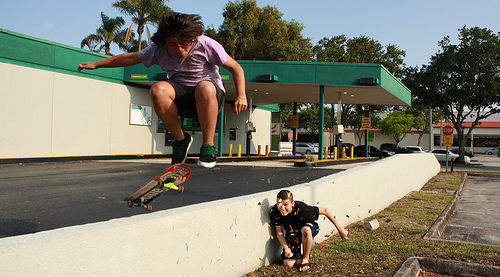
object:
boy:
[75, 12, 251, 168]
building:
[0, 29, 413, 162]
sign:
[435, 116, 453, 148]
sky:
[0, 0, 499, 118]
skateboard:
[118, 164, 193, 211]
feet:
[162, 129, 193, 169]